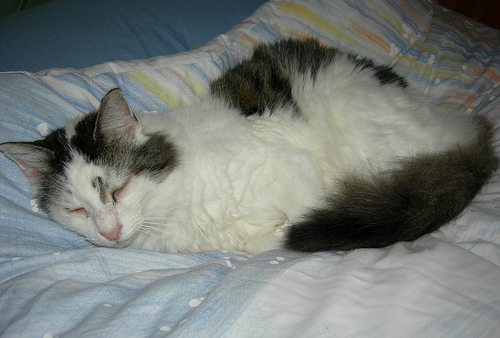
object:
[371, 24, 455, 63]
pillow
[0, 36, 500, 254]
cat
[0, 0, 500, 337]
bed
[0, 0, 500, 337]
comforter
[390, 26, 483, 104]
bleach stain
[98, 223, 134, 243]
black nose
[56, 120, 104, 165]
stripe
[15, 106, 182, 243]
head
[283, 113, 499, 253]
black tail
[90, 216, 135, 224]
pink nose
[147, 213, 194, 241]
whiskers